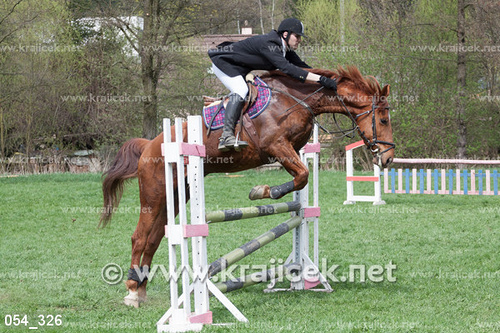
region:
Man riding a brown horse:
[205, 16, 335, 152]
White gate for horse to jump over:
[155, 100, 330, 330]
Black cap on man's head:
[276, 12, 301, 42]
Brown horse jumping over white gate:
[97, 71, 395, 306]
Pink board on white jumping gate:
[178, 142, 209, 161]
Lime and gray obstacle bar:
[191, 196, 325, 226]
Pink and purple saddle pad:
[201, 76, 273, 133]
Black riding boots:
[213, 91, 250, 152]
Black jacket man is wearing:
[207, 25, 311, 81]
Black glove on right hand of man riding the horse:
[318, 69, 339, 96]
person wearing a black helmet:
[271, 13, 304, 50]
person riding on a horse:
[205, 1, 335, 156]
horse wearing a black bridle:
[355, 87, 401, 160]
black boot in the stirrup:
[210, 91, 252, 156]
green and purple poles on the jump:
[196, 195, 307, 291]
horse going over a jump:
[86, 69, 409, 304]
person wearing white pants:
[207, 53, 252, 100]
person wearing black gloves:
[318, 73, 339, 90]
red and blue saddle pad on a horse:
[205, 70, 274, 132]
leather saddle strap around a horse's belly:
[238, 112, 270, 157]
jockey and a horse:
[94, 12, 401, 304]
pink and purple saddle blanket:
[197, 83, 270, 128]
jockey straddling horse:
[208, 10, 336, 154]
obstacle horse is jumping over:
[165, 192, 331, 312]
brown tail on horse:
[96, 127, 143, 229]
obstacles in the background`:
[343, 147, 491, 209]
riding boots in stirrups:
[218, 89, 250, 156]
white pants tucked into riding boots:
[210, 54, 250, 152]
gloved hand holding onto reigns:
[315, 67, 343, 109]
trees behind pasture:
[15, 13, 168, 130]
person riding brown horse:
[80, 20, 389, 294]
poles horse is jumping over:
[162, 93, 330, 314]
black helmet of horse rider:
[272, 13, 304, 35]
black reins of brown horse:
[294, 51, 399, 172]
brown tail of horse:
[97, 132, 137, 211]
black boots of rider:
[213, 92, 253, 147]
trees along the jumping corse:
[19, 19, 474, 146]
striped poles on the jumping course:
[205, 180, 287, 281]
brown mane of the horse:
[307, 55, 388, 95]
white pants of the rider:
[213, 61, 242, 94]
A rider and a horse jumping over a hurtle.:
[123, 15, 409, 305]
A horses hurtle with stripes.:
[161, 205, 340, 327]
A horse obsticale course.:
[346, 144, 498, 201]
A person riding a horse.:
[203, 14, 324, 144]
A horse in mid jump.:
[93, 72, 386, 290]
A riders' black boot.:
[196, 89, 278, 151]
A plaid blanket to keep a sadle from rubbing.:
[193, 90, 271, 129]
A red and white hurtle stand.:
[155, 110, 227, 330]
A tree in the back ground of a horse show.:
[110, 12, 182, 130]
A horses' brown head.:
[345, 73, 401, 168]